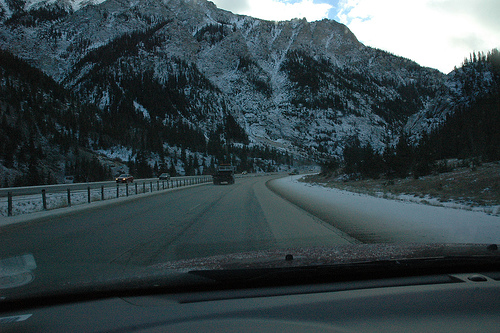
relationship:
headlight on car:
[114, 177, 117, 179] [113, 171, 133, 183]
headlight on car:
[121, 176, 126, 181] [113, 171, 133, 183]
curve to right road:
[225, 154, 325, 220] [1, 172, 364, 294]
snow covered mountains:
[184, 27, 457, 158] [63, 21, 483, 161]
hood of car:
[195, 253, 475, 328] [193, 155, 245, 185]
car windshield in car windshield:
[0, 2, 496, 301] [45, 31, 452, 234]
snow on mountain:
[271, 65, 279, 82] [3, 2, 498, 170]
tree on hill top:
[166, 72, 186, 92] [13, 20, 285, 195]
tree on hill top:
[215, 103, 257, 169] [13, 20, 285, 195]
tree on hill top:
[139, 65, 159, 107] [13, 20, 285, 195]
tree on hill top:
[158, 86, 181, 116] [13, 20, 285, 195]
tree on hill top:
[202, 125, 223, 156] [13, 20, 285, 195]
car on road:
[154, 164, 174, 187] [3, 155, 286, 217]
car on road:
[108, 171, 140, 188] [3, 155, 286, 217]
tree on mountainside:
[472, 49, 477, 67] [399, 52, 496, 141]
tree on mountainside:
[487, 50, 492, 62] [399, 52, 496, 141]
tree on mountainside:
[483, 52, 486, 62] [399, 52, 496, 141]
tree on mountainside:
[476, 50, 481, 61] [399, 52, 496, 141]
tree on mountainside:
[462, 60, 469, 69] [399, 52, 496, 141]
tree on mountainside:
[452, 66, 458, 75] [399, 52, 496, 141]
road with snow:
[1, 166, 359, 288] [268, 170, 498, 245]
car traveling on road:
[213, 166, 236, 186] [1, 172, 364, 294]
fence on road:
[32, 167, 264, 224] [1, 166, 361, 288]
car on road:
[213, 166, 236, 186] [1, 166, 359, 288]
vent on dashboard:
[170, 271, 471, 305] [109, 259, 495, 326]